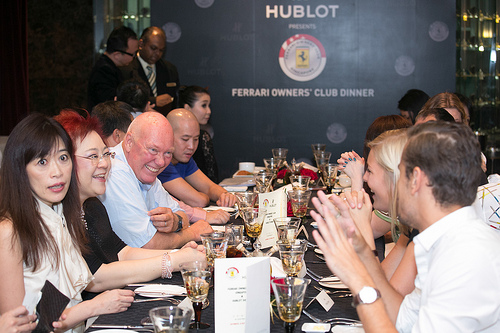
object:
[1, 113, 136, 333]
person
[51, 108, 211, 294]
person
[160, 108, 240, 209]
person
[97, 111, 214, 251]
man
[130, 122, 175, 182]
face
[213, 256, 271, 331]
menu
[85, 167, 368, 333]
table